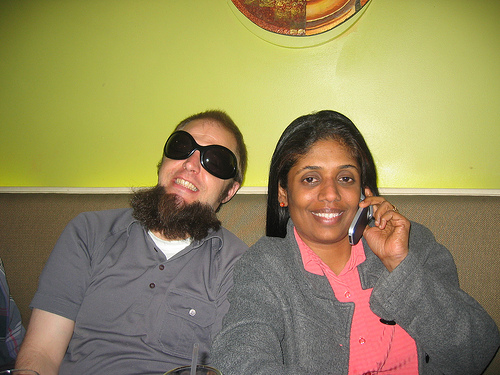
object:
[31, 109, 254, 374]
man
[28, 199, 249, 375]
shirt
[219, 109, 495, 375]
woman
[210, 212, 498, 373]
shirt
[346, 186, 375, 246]
cell phone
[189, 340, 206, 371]
straw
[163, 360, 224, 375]
cup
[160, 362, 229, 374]
rim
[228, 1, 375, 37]
art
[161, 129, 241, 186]
sunglasses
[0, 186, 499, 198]
strip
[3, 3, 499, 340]
wall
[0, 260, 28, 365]
shirt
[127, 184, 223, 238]
beard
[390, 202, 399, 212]
ring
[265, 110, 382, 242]
hair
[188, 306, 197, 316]
button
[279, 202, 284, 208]
earring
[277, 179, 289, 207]
ear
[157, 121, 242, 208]
face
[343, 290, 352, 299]
button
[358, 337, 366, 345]
button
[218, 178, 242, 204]
ear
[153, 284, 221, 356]
pocket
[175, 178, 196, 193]
teeth